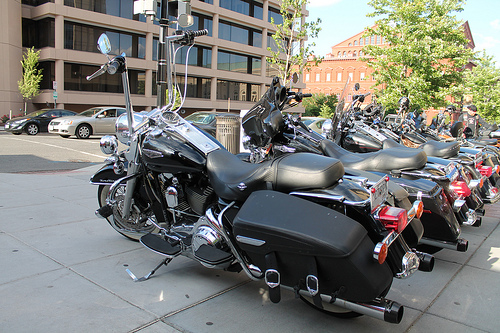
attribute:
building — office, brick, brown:
[210, 22, 283, 79]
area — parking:
[7, 67, 194, 182]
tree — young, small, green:
[370, 15, 458, 100]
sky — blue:
[329, 6, 347, 30]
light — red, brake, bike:
[368, 192, 421, 271]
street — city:
[56, 72, 444, 258]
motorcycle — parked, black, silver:
[167, 81, 445, 312]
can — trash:
[197, 103, 262, 157]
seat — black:
[195, 138, 341, 215]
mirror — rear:
[78, 24, 131, 91]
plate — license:
[385, 177, 481, 271]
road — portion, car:
[44, 101, 123, 166]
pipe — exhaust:
[325, 275, 389, 325]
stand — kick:
[112, 237, 189, 304]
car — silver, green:
[57, 88, 142, 145]